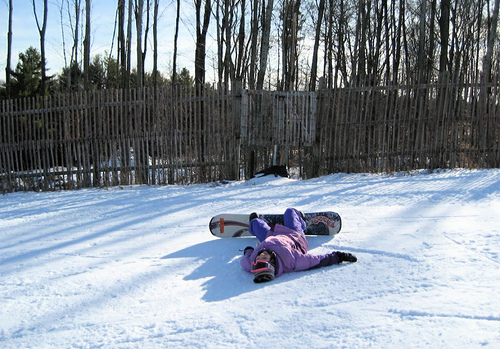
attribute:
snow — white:
[36, 170, 498, 343]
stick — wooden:
[54, 93, 64, 189]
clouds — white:
[135, 32, 206, 74]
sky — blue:
[1, 0, 499, 86]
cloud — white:
[267, 37, 327, 86]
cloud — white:
[143, 38, 220, 83]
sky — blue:
[159, 1, 340, 68]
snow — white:
[319, 307, 331, 328]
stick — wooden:
[215, 77, 272, 154]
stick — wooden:
[129, 84, 147, 184]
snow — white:
[384, 299, 477, 327]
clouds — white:
[297, 35, 323, 73]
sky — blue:
[0, 0, 498, 102]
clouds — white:
[58, 17, 240, 83]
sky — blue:
[9, 11, 444, 93]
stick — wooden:
[429, 62, 443, 171]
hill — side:
[2, 169, 498, 347]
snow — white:
[63, 222, 115, 299]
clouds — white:
[111, 26, 266, 94]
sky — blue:
[37, 12, 499, 127]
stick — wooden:
[211, 81, 220, 184]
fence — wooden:
[34, 78, 494, 202]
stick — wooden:
[354, 75, 363, 172]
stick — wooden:
[26, 97, 36, 192]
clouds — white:
[35, 50, 139, 63]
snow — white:
[51, 217, 174, 349]